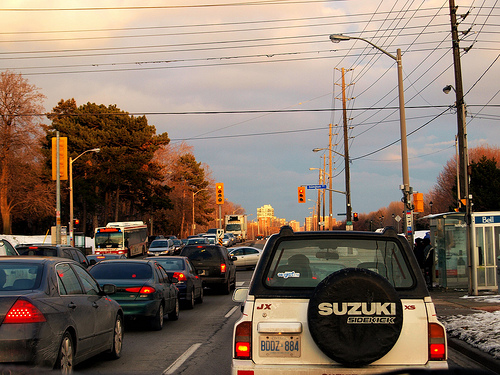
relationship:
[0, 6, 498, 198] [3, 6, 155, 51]
sky with clouds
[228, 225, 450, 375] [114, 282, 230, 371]
car sitting on road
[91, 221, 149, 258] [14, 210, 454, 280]
bus parked on side of road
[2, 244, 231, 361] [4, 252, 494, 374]
cars sitting in road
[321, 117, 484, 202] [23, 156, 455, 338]
poles sitting by road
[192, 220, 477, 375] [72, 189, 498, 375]
rear view of white suzuki truck in traffic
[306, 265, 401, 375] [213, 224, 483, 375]
black covered spare tire with white letters reading suzuki on back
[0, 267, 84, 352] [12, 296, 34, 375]
blue sedan stopped with brake light lit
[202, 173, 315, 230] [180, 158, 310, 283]
two yellow traiic lights indicating stop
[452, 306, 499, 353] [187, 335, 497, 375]
snow melting on sidewalk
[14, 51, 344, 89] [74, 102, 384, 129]
ominous sky indicating storm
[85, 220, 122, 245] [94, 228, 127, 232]
bus with orange digitel display across top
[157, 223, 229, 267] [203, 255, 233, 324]
suv truck stopped at light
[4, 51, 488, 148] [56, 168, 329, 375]
electrical power lines above street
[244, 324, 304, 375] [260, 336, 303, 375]
license with blue numbers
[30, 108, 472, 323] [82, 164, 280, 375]
view in street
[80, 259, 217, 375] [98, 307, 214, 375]
road made of ashphalt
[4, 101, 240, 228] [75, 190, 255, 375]
trees are next to road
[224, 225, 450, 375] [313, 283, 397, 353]
car a model of suzuki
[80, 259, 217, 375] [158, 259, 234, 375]
road has a white lane in middle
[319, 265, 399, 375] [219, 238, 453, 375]
tire on back of white truck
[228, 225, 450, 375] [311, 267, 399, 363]
car has a black tire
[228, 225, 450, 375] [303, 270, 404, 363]
car has a black tire